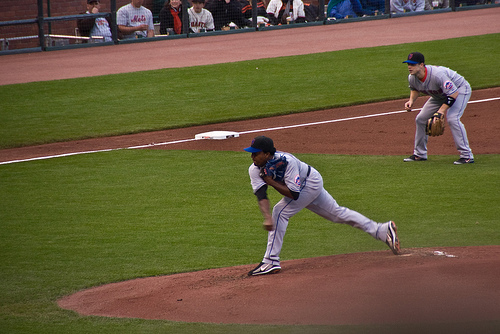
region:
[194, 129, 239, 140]
A white square base.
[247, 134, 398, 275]
A pitcher in a white uniform.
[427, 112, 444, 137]
Brown glove on a player.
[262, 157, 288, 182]
A blue glove.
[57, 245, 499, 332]
A dirt pitchers mound.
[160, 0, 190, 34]
Woman sitting with an orange scarf.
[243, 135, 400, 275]
a baseball pitcher throwing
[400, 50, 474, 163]
a baseball player on field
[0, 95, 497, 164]
a white marked foul line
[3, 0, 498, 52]
a baseball stadium dugout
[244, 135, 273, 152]
a blue and black baseball cap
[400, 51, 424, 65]
a blue and black baseball cap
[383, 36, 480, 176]
a baseball player watching a play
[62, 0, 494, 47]
a row of players in a dugout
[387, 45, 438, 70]
a baseball player's hat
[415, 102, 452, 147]
a baseball player's brown glove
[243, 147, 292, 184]
a baseball player's blue glove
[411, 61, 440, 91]
the collar of a red shirt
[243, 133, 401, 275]
Baseball pitcher who has just thrown ball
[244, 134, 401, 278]
Baseball player in white uniform and black cap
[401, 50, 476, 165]
Baseball player crouching in infield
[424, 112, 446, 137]
Baseball glove on player's left hand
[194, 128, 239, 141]
Baseball base sitting on white line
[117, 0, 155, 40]
Man wearing Mets T-shirt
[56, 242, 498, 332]
Pitcher's mound of bare dirt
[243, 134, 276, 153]
Black baseball cap with blue brim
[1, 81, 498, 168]
Baseball path of bare dirt in green grass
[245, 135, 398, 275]
baseball pitcher throwing a ball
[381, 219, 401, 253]
baseball pitcher's left shoe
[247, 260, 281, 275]
baseball pitcher's right shoe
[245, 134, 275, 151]
black cap with blue rim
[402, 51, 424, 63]
black cap with blue rim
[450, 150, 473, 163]
a ball player's left foot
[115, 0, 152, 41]
spectator at a ball game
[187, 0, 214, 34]
spectator at a ball game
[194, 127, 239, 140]
White square base.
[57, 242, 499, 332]
Brown dirt pitchers mound.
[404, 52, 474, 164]
Player in grey leaning over with brown glove.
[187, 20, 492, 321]
people playing baseball.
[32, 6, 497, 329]
A grass and dirt baseball field.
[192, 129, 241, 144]
A white base.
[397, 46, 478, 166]
A person squatting down.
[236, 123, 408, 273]
A person with their back leg extended.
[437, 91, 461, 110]
A black and white wristband.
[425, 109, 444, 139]
A brown baseball glove.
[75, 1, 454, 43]
Spectators.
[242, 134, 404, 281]
a baseball pitcher.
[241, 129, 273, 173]
the head of a man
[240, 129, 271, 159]
the hat of a man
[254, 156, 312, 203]
the left arm of a man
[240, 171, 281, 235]
the right arm of a man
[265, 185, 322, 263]
the left leg of a man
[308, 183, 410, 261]
the right leg of a man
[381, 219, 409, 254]
the right foot of a man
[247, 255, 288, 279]
the right foot of a man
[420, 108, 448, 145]
the glove of a man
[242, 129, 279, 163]
the pitcher's hat is black and blue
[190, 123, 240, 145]
the base is white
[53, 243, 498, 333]
the pitcher's mound is brown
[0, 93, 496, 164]
the line is white